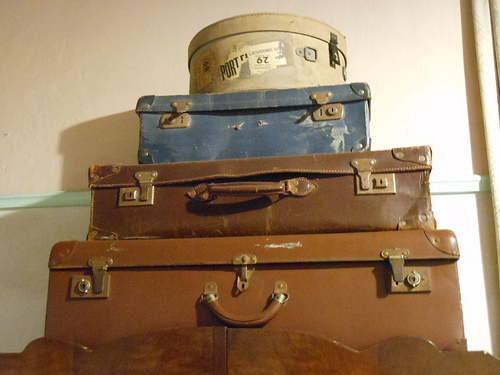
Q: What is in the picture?
A: Suitcases.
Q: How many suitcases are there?
A: 4.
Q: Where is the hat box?
A: On top.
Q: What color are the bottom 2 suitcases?
A: Brown.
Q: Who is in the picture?
A: Nobody.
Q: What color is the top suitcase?
A: White.